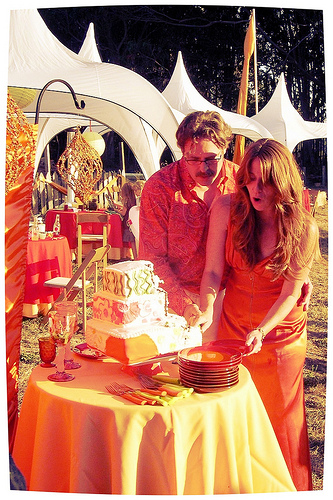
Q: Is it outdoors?
A: Yes, it is outdoors.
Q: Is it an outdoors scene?
A: Yes, it is outdoors.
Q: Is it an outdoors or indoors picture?
A: It is outdoors.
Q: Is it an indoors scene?
A: No, it is outdoors.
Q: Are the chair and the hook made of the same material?
A: No, the chair is made of wood and the hook is made of metal.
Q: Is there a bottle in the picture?
A: No, there are no bottles.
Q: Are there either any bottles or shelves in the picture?
A: No, there are no bottles or shelves.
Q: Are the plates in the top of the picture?
A: No, the plates are in the bottom of the image.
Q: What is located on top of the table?
A: The plates are on top of the table.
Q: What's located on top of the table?
A: The plates are on top of the table.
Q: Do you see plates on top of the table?
A: Yes, there are plates on top of the table.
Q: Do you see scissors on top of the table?
A: No, there are plates on top of the table.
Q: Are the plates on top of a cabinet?
A: No, the plates are on top of the table.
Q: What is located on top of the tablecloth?
A: The plates are on top of the tablecloth.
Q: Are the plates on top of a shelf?
A: No, the plates are on top of the tablecloth.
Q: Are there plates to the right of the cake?
A: Yes, there are plates to the right of the cake.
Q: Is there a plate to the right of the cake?
A: Yes, there are plates to the right of the cake.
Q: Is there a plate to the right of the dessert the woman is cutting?
A: Yes, there are plates to the right of the cake.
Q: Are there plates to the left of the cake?
A: No, the plates are to the right of the cake.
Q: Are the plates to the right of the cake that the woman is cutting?
A: Yes, the plates are to the right of the cake.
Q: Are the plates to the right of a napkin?
A: No, the plates are to the right of the cake.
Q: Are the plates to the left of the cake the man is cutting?
A: No, the plates are to the right of the cake.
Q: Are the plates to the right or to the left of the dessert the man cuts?
A: The plates are to the right of the cake.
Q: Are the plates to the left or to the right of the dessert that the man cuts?
A: The plates are to the right of the cake.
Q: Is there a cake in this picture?
A: Yes, there is a cake.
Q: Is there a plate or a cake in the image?
A: Yes, there is a cake.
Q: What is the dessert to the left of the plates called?
A: The dessert is a cake.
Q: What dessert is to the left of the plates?
A: The dessert is a cake.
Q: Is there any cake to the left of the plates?
A: Yes, there is a cake to the left of the plates.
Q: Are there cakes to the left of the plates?
A: Yes, there is a cake to the left of the plates.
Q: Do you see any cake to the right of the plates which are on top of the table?
A: No, the cake is to the left of the plates.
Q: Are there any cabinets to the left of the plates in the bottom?
A: No, there is a cake to the left of the plates.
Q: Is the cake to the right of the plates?
A: No, the cake is to the left of the plates.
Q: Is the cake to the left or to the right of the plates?
A: The cake is to the left of the plates.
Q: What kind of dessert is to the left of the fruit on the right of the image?
A: The dessert is a cake.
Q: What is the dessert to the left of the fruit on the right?
A: The dessert is a cake.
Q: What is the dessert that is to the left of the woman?
A: The dessert is a cake.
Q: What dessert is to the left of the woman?
A: The dessert is a cake.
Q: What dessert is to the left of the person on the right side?
A: The dessert is a cake.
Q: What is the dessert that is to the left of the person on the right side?
A: The dessert is a cake.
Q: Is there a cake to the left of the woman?
A: Yes, there is a cake to the left of the woman.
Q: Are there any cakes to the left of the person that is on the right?
A: Yes, there is a cake to the left of the woman.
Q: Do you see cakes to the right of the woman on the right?
A: No, the cake is to the left of the woman.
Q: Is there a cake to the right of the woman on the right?
A: No, the cake is to the left of the woman.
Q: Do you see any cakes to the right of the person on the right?
A: No, the cake is to the left of the woman.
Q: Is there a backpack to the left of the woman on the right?
A: No, there is a cake to the left of the woman.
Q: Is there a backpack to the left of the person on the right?
A: No, there is a cake to the left of the woman.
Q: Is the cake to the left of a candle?
A: No, the cake is to the left of the woman.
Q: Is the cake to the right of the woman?
A: No, the cake is to the left of the woman.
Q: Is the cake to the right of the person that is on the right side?
A: No, the cake is to the left of the woman.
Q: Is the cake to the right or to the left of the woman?
A: The cake is to the left of the woman.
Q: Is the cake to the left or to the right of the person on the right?
A: The cake is to the left of the woman.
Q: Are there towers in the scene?
A: No, there are no towers.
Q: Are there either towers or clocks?
A: No, there are no towers or clocks.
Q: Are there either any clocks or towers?
A: No, there are no towers or clocks.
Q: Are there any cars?
A: No, there are no cars.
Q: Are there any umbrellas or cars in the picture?
A: No, there are no cars or umbrellas.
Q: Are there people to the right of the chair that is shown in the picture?
A: Yes, there are people to the right of the chair.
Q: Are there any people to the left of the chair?
A: No, the people are to the right of the chair.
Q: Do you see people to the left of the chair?
A: No, the people are to the right of the chair.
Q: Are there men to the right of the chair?
A: Yes, there is a man to the right of the chair.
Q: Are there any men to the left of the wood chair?
A: No, the man is to the right of the chair.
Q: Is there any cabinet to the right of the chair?
A: No, there is a man to the right of the chair.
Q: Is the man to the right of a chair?
A: Yes, the man is to the right of a chair.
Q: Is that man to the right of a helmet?
A: No, the man is to the right of a chair.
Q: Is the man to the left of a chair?
A: No, the man is to the right of a chair.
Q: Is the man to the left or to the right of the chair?
A: The man is to the right of the chair.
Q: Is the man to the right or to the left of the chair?
A: The man is to the right of the chair.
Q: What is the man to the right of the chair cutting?
A: The man is cutting the cake.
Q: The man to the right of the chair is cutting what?
A: The man is cutting the cake.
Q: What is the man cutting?
A: The man is cutting the cake.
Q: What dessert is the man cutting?
A: The man is cutting the cake.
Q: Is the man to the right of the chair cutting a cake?
A: Yes, the man is cutting a cake.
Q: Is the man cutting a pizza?
A: No, the man is cutting a cake.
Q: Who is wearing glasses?
A: The man is wearing glasses.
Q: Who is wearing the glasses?
A: The man is wearing glasses.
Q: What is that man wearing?
A: The man is wearing glasses.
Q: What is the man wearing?
A: The man is wearing glasses.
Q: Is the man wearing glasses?
A: Yes, the man is wearing glasses.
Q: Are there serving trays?
A: No, there are no serving trays.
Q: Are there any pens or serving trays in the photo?
A: No, there are no serving trays or pens.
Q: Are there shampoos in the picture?
A: No, there are no shampoos.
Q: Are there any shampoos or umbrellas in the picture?
A: No, there are no shampoos or umbrellas.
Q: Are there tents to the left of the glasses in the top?
A: Yes, there are tents to the left of the glasses.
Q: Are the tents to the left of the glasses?
A: Yes, the tents are to the left of the glasses.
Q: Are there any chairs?
A: Yes, there is a chair.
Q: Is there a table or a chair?
A: Yes, there is a chair.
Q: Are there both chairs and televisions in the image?
A: No, there is a chair but no televisions.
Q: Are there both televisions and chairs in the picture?
A: No, there is a chair but no televisions.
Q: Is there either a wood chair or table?
A: Yes, there is a wood chair.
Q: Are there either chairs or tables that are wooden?
A: Yes, the chair is wooden.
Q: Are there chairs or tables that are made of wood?
A: Yes, the chair is made of wood.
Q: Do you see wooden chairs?
A: Yes, there is a wood chair.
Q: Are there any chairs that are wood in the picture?
A: Yes, there is a wood chair.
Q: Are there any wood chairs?
A: Yes, there is a wood chair.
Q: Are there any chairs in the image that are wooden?
A: Yes, there is a chair that is wooden.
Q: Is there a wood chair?
A: Yes, there is a chair that is made of wood.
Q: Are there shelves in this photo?
A: No, there are no shelves.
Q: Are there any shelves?
A: No, there are no shelves.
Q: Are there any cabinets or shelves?
A: No, there are no shelves or cabinets.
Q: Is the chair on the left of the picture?
A: Yes, the chair is on the left of the image.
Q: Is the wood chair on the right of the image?
A: No, the chair is on the left of the image.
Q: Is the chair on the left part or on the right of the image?
A: The chair is on the left of the image.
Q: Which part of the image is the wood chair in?
A: The chair is on the left of the image.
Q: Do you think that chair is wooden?
A: Yes, the chair is wooden.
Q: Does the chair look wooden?
A: Yes, the chair is wooden.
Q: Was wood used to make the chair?
A: Yes, the chair is made of wood.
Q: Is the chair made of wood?
A: Yes, the chair is made of wood.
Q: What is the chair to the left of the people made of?
A: The chair is made of wood.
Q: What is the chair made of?
A: The chair is made of wood.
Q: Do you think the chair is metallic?
A: No, the chair is wooden.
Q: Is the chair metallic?
A: No, the chair is wooden.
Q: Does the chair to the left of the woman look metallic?
A: No, the chair is wooden.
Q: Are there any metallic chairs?
A: No, there is a chair but it is wooden.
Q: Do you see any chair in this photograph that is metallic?
A: No, there is a chair but it is wooden.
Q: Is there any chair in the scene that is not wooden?
A: No, there is a chair but it is wooden.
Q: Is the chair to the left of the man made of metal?
A: No, the chair is made of wood.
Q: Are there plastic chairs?
A: No, there is a chair but it is made of wood.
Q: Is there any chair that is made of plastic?
A: No, there is a chair but it is made of wood.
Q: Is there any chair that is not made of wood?
A: No, there is a chair but it is made of wood.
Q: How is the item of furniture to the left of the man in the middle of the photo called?
A: The piece of furniture is a chair.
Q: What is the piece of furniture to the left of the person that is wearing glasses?
A: The piece of furniture is a chair.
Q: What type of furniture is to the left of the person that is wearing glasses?
A: The piece of furniture is a chair.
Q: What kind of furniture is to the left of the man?
A: The piece of furniture is a chair.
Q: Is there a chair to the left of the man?
A: Yes, there is a chair to the left of the man.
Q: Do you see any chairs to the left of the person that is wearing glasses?
A: Yes, there is a chair to the left of the man.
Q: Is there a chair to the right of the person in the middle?
A: No, the chair is to the left of the man.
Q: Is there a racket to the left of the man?
A: No, there is a chair to the left of the man.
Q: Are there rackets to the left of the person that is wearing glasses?
A: No, there is a chair to the left of the man.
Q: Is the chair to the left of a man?
A: Yes, the chair is to the left of a man.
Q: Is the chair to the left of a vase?
A: No, the chair is to the left of a man.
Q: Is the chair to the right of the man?
A: No, the chair is to the left of the man.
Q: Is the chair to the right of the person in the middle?
A: No, the chair is to the left of the man.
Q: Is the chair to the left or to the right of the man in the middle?
A: The chair is to the left of the man.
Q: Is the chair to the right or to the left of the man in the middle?
A: The chair is to the left of the man.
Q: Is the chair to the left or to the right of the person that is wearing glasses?
A: The chair is to the left of the man.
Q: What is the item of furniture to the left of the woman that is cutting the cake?
A: The piece of furniture is a chair.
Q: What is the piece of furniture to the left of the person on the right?
A: The piece of furniture is a chair.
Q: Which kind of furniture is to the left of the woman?
A: The piece of furniture is a chair.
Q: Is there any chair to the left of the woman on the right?
A: Yes, there is a chair to the left of the woman.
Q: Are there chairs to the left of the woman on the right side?
A: Yes, there is a chair to the left of the woman.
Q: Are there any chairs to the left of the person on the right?
A: Yes, there is a chair to the left of the woman.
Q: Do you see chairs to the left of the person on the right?
A: Yes, there is a chair to the left of the woman.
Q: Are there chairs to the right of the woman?
A: No, the chair is to the left of the woman.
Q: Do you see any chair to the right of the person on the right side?
A: No, the chair is to the left of the woman.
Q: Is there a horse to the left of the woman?
A: No, there is a chair to the left of the woman.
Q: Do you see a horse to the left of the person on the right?
A: No, there is a chair to the left of the woman.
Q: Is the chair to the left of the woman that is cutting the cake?
A: Yes, the chair is to the left of the woman.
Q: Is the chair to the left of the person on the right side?
A: Yes, the chair is to the left of the woman.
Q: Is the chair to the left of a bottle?
A: No, the chair is to the left of the woman.